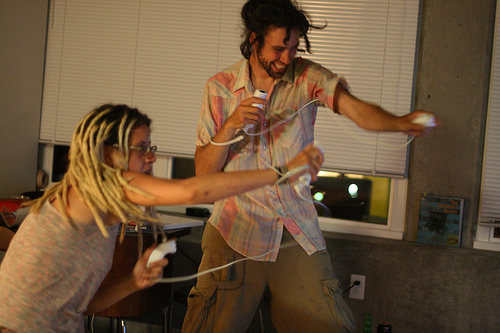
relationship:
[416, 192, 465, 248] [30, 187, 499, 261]
book on ledge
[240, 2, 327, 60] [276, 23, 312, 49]
hair has part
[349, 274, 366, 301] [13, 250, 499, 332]
socket on wall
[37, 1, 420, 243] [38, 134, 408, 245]
window has bottom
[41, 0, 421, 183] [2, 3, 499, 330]
blinds in room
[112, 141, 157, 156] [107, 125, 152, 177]
glasses on face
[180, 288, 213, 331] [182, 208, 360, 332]
pocket on pants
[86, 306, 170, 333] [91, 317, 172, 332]
legs have bottom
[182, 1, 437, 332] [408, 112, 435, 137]
man playing wii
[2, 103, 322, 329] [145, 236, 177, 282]
woman playing wii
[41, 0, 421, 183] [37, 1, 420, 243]
blinds on window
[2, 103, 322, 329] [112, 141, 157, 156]
woman wearing glasses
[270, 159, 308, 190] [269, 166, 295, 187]
strap around wrist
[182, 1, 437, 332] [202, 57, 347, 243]
man wearing shirt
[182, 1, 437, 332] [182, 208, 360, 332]
man wearing shorts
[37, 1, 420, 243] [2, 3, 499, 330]
window in room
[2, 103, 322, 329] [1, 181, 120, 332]
woman wearing top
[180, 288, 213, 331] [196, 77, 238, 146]
pocket on sleeve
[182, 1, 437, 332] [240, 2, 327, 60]
man has hair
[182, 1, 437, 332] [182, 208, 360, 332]
man wearing pants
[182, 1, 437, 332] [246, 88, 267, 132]
man holding controller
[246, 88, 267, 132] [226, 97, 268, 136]
controller in hand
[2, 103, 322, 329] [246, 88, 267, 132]
woman holding controller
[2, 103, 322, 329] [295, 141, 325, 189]
woman holding controller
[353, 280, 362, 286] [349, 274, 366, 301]
plug in socket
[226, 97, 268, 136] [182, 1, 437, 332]
hand in front of man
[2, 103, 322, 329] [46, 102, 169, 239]
woman has hair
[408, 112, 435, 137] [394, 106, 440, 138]
remote in hand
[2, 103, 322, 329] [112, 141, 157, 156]
woman wearing spectacles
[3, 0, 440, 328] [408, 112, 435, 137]
couple playing wii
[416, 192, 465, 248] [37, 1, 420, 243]
book near window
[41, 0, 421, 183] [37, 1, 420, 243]
blinds over window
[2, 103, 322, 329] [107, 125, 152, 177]
woman has face